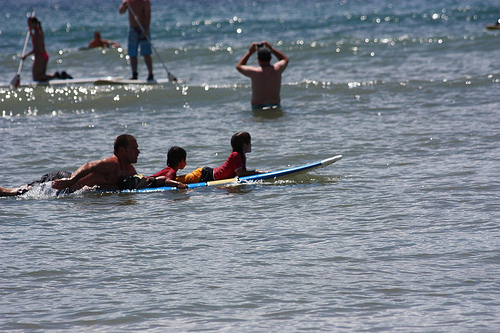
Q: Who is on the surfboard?
A: A man and two children.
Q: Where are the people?
A: In the water.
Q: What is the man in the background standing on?
A: A paddle board.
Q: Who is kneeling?
A: A woman on a paddleboard.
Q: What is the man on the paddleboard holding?
A: An oar.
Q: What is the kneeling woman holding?
A: An oar.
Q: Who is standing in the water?
A: A man.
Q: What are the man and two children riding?
A: A surfboard.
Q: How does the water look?
A: Glistening and slightly wavy.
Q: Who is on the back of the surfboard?
A: A man.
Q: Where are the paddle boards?
A: Water.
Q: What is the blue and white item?
A: Surfboard.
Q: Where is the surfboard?
A: In water.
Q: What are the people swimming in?
A: Water.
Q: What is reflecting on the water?
A: Light.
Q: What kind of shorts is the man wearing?
A: Blue.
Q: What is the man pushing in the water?
A: Children.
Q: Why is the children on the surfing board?
A: To surf.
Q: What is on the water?
A: Surfboard.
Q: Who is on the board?
A: A man and kids.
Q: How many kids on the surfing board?
A: Two.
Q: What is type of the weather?
A: Sunny.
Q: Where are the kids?
A: On the water.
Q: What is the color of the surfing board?
A: Blue.